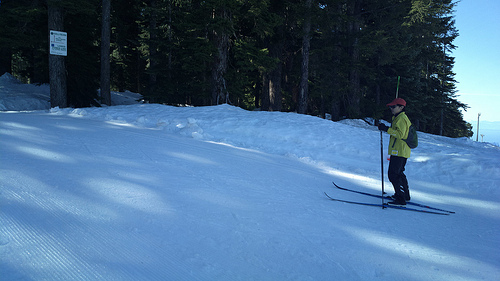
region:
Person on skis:
[321, 176, 459, 219]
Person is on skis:
[320, 177, 461, 220]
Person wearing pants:
[381, 155, 413, 193]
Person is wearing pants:
[384, 152, 407, 185]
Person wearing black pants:
[386, 152, 411, 201]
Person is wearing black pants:
[384, 154, 412, 196]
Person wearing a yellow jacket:
[382, 112, 417, 162]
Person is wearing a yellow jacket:
[388, 110, 413, 160]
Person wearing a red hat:
[385, 94, 408, 108]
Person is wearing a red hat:
[385, 92, 411, 108]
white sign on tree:
[50, 24, 70, 59]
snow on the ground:
[142, 176, 202, 248]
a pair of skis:
[319, 172, 467, 243]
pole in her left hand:
[374, 120, 391, 207]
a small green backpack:
[406, 121, 419, 152]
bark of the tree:
[204, 33, 229, 97]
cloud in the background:
[456, 77, 496, 124]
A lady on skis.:
[324, 97, 457, 215]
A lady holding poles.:
[374, 97, 421, 208]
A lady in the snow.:
[373, 96, 418, 202]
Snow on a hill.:
[1, 70, 498, 278]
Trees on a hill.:
[3, 3, 475, 140]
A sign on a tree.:
[48, 28, 70, 59]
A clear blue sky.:
[423, 2, 499, 144]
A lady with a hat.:
[372, 96, 419, 206]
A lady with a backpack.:
[377, 98, 419, 205]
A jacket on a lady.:
[384, 111, 411, 160]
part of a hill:
[328, 163, 337, 180]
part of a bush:
[327, 73, 337, 94]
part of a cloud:
[364, 115, 376, 120]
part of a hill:
[198, 166, 213, 192]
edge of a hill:
[169, 188, 208, 248]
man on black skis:
[322, 86, 456, 220]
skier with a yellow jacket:
[328, 85, 453, 222]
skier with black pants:
[317, 92, 463, 218]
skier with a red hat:
[318, 89, 461, 220]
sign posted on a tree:
[43, 25, 77, 61]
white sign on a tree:
[43, 24, 77, 59]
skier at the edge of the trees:
[316, 95, 461, 218]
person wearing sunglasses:
[330, 92, 454, 224]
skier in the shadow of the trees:
[329, 82, 464, 228]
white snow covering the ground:
[1, 77, 498, 276]